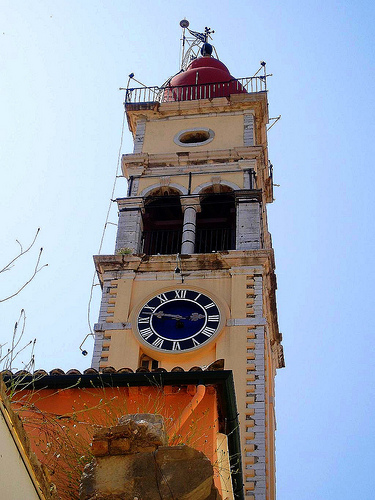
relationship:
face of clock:
[149, 302, 205, 338] [135, 286, 220, 352]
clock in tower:
[135, 286, 220, 352] [84, 16, 283, 498]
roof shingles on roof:
[167, 365, 200, 375] [77, 351, 237, 434]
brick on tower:
[245, 270, 266, 287] [84, 16, 283, 498]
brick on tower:
[245, 288, 265, 298] [84, 16, 283, 498]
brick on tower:
[246, 334, 268, 346] [84, 16, 283, 498]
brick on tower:
[241, 398, 268, 413] [84, 16, 283, 498]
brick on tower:
[241, 460, 267, 471] [84, 16, 283, 498]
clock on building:
[135, 286, 220, 352] [3, 17, 294, 497]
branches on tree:
[2, 229, 161, 499] [2, 215, 98, 495]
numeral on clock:
[166, 335, 184, 352] [135, 286, 220, 352]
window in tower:
[176, 123, 211, 150] [84, 16, 283, 498]